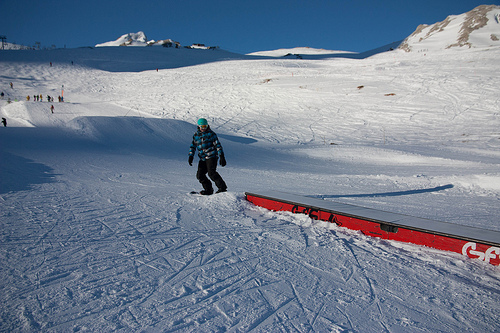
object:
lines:
[243, 292, 300, 332]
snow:
[94, 30, 179, 47]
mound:
[395, 3, 500, 52]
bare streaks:
[397, 23, 430, 52]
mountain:
[245, 45, 354, 56]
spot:
[357, 85, 365, 89]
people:
[10, 81, 14, 89]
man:
[187, 117, 228, 194]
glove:
[187, 153, 195, 166]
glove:
[219, 152, 227, 167]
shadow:
[303, 183, 462, 203]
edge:
[244, 191, 500, 248]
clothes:
[188, 124, 229, 192]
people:
[0, 116, 8, 127]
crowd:
[0, 81, 65, 127]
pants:
[195, 156, 228, 190]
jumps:
[67, 115, 202, 144]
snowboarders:
[46, 94, 52, 102]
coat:
[188, 124, 225, 162]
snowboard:
[189, 190, 211, 199]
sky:
[0, 0, 500, 55]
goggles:
[199, 124, 209, 129]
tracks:
[136, 254, 198, 305]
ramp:
[243, 186, 500, 267]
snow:
[0, 9, 500, 333]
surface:
[244, 188, 499, 247]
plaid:
[187, 131, 225, 161]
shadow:
[0, 112, 260, 160]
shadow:
[1, 148, 65, 196]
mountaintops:
[117, 29, 150, 41]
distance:
[0, 0, 500, 102]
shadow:
[0, 39, 408, 75]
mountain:
[0, 40, 43, 51]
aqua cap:
[197, 118, 209, 130]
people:
[49, 104, 55, 115]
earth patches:
[383, 92, 397, 97]